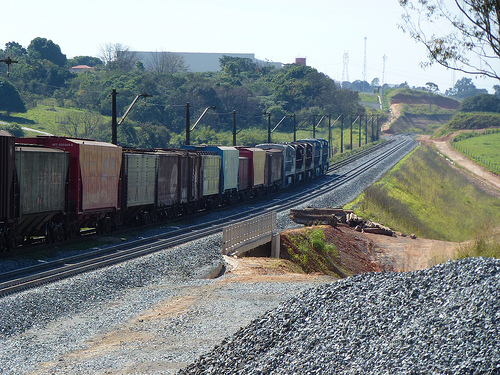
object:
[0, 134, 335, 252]
freight car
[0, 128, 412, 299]
track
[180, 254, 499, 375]
pile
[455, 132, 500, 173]
field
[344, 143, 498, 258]
slope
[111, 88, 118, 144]
pole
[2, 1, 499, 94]
sky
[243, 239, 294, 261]
culvert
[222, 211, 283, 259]
bridge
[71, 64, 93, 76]
building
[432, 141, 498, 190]
road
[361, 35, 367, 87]
tower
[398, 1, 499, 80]
tree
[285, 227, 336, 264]
grass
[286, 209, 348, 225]
logs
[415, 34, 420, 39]
leaf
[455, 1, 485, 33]
branch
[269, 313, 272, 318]
rock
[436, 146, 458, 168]
fence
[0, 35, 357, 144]
forest